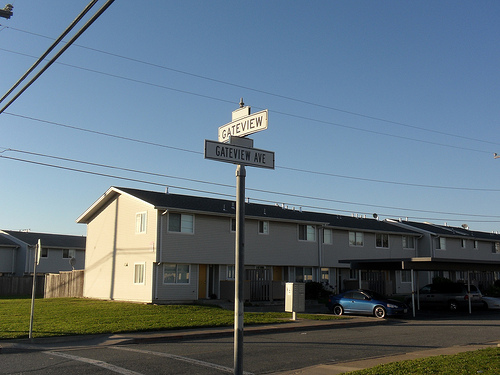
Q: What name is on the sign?
A: Gateview.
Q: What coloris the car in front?
A: Blue.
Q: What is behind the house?
A: A fence.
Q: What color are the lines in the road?
A: White.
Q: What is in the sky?
A: Electrical wires.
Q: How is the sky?
A: Cloudless.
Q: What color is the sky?
A: Blue.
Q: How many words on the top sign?
A: 1.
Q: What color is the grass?
A: Green.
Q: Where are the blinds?
A: In the windows.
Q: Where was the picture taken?
A: An apartment complex.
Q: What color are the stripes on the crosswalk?
A: White.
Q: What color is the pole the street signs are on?
A: Grey.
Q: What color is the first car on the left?
A: Blue.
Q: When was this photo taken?
A: Daytime.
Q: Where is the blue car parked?
A: In the driveway.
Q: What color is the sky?
A: Blue.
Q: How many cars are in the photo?
A: Three.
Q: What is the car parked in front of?
A: Apartment building.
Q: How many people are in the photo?
A: Zero.